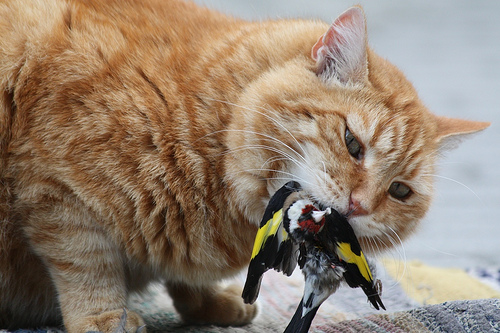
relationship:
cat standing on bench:
[5, 2, 492, 332] [2, 264, 495, 332]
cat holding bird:
[5, 2, 492, 332] [236, 180, 383, 332]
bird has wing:
[236, 180, 383, 332] [238, 186, 290, 307]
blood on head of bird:
[301, 205, 326, 238] [236, 180, 383, 332]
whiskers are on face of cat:
[195, 86, 344, 209] [5, 2, 492, 332]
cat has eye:
[5, 2, 492, 332] [343, 123, 366, 163]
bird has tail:
[236, 180, 383, 332] [282, 289, 331, 332]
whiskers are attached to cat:
[195, 86, 344, 209] [5, 2, 492, 332]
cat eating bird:
[5, 2, 492, 332] [236, 180, 383, 332]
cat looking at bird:
[5, 2, 492, 332] [236, 180, 383, 332]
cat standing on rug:
[5, 2, 492, 332] [2, 264, 495, 332]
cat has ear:
[5, 2, 492, 332] [301, 6, 369, 86]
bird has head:
[236, 180, 383, 332] [285, 202, 333, 242]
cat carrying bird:
[5, 2, 492, 332] [236, 180, 383, 332]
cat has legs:
[5, 2, 492, 332] [13, 194, 247, 331]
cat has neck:
[5, 2, 492, 332] [204, 27, 270, 242]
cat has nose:
[5, 2, 492, 332] [347, 191, 376, 219]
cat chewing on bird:
[5, 2, 492, 332] [236, 180, 383, 332]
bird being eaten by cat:
[236, 180, 383, 332] [5, 2, 492, 332]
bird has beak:
[236, 180, 383, 332] [311, 203, 333, 222]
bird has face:
[236, 180, 383, 332] [289, 200, 328, 239]